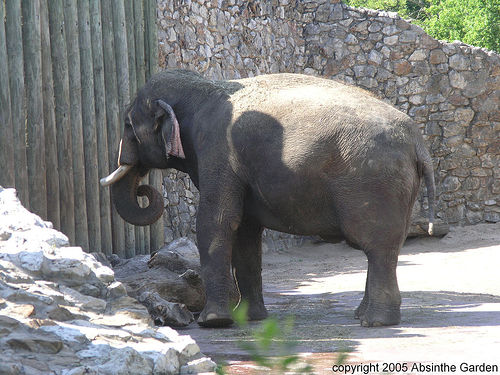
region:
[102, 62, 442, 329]
A small baby elephant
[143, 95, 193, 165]
The gray and pink ear of a baby elephant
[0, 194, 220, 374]
A small formation of rocks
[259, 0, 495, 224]
A tall rocky wall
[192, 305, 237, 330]
The foot of an elephant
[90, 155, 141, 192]
An elephant's small tusk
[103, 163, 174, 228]
An elephant's curled trunk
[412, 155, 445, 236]
An elephant's ear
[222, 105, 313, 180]
The shadow of man's head cast on an elephant's back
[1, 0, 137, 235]
A wooden door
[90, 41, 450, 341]
Elephant in a zoo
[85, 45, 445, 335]
Elephant with tusks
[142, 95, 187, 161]
Ear of an elephant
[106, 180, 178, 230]
Trunk of an elephant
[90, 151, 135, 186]
Tusk of an elephant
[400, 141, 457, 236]
Tail of an elephant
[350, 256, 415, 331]
Back legs of an elephant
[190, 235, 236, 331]
Front leg of an elephant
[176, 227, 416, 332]
Legs of an elephant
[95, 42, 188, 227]
Head of an elephant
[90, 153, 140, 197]
White ivory elephant tusk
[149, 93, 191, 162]
Big flappy elephant ear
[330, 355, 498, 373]
Black printed photo watermark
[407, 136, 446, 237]
Short, grey elephant tail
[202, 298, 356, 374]
Small tree limb in photo foreground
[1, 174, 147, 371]
Jumble of white and grey rocks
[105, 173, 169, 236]
Curled, prehensile elephant trunk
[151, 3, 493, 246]
Rock wall of the elephant enclosure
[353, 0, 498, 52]
Trees in the background behind the rock wall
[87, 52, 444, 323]
Grey elephant in a zoo enclosure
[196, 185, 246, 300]
the leg of an elephant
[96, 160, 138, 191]
a white elephant tusk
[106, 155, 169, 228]
the trunk of an elephant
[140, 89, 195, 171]
the ear of an elephant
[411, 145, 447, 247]
the tail of an elephant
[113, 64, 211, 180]
the head of an elephant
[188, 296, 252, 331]
the foot of an elephant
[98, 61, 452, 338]
an elephant on the ground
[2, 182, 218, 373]
a large gray rock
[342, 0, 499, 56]
green plants next to the wall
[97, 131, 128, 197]
white tusk on left of elephant's face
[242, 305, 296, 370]
greenery in bottom center of photo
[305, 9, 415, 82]
stone wall on right of elephant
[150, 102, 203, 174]
elephant's left ear with pink center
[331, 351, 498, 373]
copyright 2005 Absinthe Gardern located on right lower corner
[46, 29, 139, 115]
wooden verticle log fence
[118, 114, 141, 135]
left eye on front of elephant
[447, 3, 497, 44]
green trees located outside of the stone wall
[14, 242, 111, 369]
white pile of stones to the left of elephant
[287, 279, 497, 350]
dark shadow of elephant